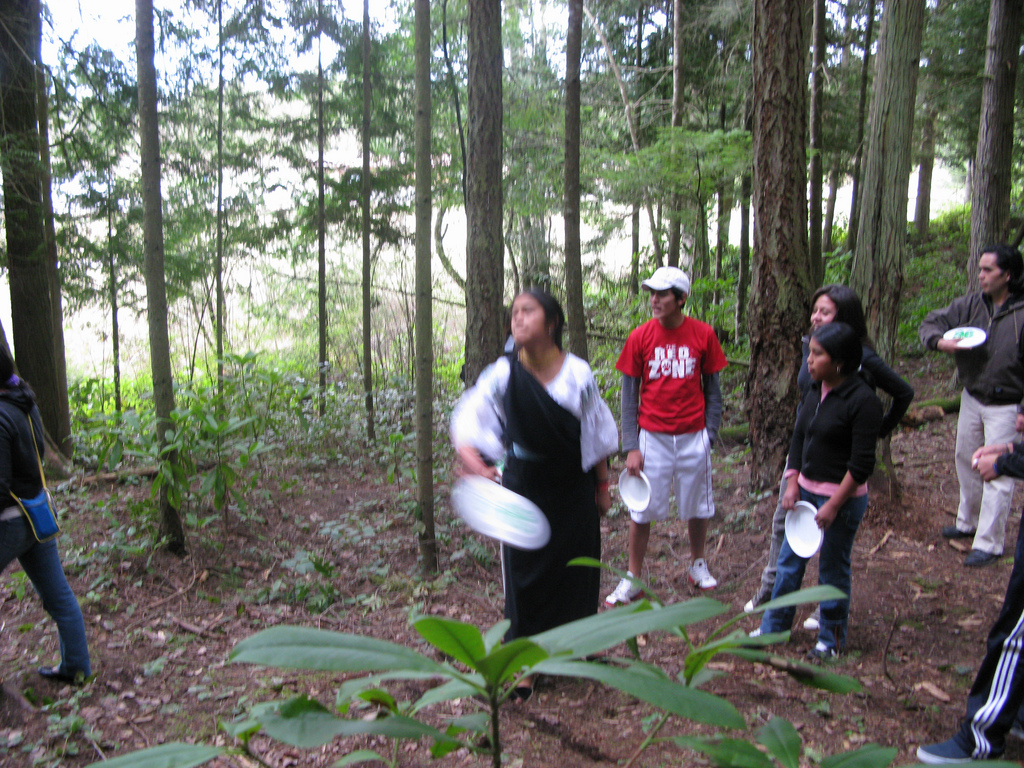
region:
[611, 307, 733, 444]
"RED ZONE" written on red shirt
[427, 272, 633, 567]
A woman about to throw a frisbee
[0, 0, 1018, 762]
People standing in a forest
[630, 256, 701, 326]
White hat on a guy's head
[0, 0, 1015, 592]
Green leaves on many thin trees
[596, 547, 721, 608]
A pair of white sneakers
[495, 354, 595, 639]
Woman is wearing a black dress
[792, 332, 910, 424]
Woman is wearing a black shirt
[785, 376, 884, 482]
Girl is wearing a black shirt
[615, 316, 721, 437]
Man is wearing a red shirt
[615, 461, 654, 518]
Man is holding a white plate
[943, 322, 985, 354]
Man is holding a white plate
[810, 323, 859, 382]
Woman has dark hair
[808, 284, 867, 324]
Woman has dark hair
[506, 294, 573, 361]
Person has dark hair.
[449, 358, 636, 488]
Person wearing white shirt.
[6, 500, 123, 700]
Person wearing blue jeans.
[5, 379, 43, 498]
Person wearing black shirt.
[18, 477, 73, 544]
Blue bag near person's bottom.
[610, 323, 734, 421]
Person wearing red shirt.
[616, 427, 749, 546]
Person wearing white shorts.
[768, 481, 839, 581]
Person holding frisbee in hands.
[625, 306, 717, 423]
The man is wearing a red and white shirt.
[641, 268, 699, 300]
The cap is white.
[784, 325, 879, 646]
The girl is holding a frisbee.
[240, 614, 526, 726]
Green leaves on the plant.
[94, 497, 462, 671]
Dirt and broken branches on the ground.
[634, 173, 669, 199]
green leaves on the tree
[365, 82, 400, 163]
green leaves on the tree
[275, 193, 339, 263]
green leaves on the tree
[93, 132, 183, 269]
green leaves on the tree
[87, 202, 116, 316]
green leaves on the tree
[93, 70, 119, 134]
green leaves on the tree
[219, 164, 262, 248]
green leaves on the tree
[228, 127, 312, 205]
green leaves on the tree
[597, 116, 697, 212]
green leaves on the tree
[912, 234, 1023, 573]
A man is throwing a white and green frisbee.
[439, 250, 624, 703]
A lady in a white and black dress is throwing a frisbee.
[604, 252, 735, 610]
The man has a red shirt with grey sleeves.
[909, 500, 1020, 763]
A leg with black and white pants is visible.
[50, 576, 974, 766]
A large green plant is in the foreground.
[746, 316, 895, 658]
A woman with a black sweater is holding a frisbee.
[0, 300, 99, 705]
Someone has a blue and yellow carrying case over their shoulder.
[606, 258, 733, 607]
A man is wearing a white hat.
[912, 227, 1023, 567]
A man is wearing a brown jacket and khaki pants.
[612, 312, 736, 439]
A red t-shirt has white writing saying The Red Zone on it.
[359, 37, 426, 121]
green leaves on the tree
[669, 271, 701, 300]
green leaves on the tree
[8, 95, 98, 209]
green leaves on the tree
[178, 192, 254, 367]
green leaves on the tree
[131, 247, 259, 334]
green leaves on the tree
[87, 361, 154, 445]
green leaves on the tree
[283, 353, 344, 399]
green leaves on the tree